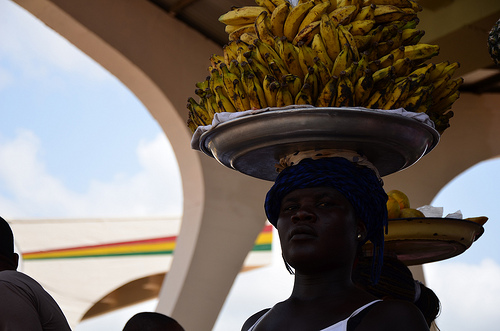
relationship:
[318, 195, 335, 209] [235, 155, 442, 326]
eye of girl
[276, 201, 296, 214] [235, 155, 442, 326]
eye of girl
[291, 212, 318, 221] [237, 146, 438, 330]
girl nose of girl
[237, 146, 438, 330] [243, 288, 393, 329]
girl wearing tank top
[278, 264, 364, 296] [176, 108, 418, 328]
neck of girl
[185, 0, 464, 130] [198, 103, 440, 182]
bananas stacked on plate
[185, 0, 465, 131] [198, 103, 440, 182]
bananas on plate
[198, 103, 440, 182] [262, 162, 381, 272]
plate on head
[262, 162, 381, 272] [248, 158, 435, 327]
head on woman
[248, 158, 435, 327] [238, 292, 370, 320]
woman wearing tank top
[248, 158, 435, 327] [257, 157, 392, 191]
woman wearing scarf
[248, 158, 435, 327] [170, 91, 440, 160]
woman wearing plate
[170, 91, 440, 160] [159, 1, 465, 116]
plate of bananas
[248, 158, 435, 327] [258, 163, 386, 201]
woman wearing head wrap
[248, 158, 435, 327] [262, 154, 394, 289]
woman wearing cloth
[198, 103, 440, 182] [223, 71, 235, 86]
plate filled with banana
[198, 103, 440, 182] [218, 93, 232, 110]
plate filled with banana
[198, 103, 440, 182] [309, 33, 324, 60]
plate filled with banana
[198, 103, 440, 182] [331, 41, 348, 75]
plate filled with banana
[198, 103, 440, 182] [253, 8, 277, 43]
plate filled with banana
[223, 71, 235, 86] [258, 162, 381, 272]
banana resting on head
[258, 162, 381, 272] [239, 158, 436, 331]
head of woman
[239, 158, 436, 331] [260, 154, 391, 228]
woman wearing wrap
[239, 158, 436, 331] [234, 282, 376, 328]
woman wearing tank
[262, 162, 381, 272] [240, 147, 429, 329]
head of person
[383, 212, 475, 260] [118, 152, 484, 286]
plate in background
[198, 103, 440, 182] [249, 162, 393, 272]
plate on head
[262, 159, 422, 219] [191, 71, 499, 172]
headscarf below platter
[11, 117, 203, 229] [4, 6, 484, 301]
clouds on left side of photo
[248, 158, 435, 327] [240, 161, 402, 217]
woman wearing bandana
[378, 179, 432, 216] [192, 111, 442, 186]
papayas on tray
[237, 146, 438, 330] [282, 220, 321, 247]
girl has lips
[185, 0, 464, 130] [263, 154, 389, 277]
bananas on lady`s head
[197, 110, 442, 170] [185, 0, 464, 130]
silver tray holding bananas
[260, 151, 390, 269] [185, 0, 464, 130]
cloth under bananas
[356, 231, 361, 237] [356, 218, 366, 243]
earring in ear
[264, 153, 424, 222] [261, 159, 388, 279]
blue scarf wrap on girl's head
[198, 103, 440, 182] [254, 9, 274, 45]
plate filled with a stack of banana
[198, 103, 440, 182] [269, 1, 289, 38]
plate filled with a stack of banana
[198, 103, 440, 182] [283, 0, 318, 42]
plate filled with a stack of banana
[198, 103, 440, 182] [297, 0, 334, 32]
plate filled with a stack of banana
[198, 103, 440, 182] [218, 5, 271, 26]
plate filled with a stack of banana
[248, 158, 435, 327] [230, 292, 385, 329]
woman wearing a tank top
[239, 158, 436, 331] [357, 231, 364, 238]
woman wearing an earrings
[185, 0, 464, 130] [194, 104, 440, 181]
bananas carried on a tray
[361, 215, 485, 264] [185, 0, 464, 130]
yellow tray with some bananas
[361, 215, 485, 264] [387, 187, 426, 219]
yellow tray with some bananas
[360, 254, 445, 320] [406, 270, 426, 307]
braids secured by white band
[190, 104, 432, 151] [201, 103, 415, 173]
cloth inside tray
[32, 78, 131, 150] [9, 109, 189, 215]
blue sky with cloud